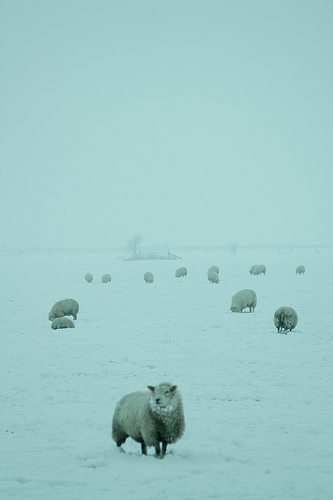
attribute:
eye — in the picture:
[165, 390, 170, 397]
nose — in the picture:
[151, 398, 169, 411]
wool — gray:
[239, 293, 251, 302]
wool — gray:
[284, 308, 297, 314]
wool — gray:
[62, 300, 72, 306]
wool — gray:
[58, 318, 66, 322]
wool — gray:
[210, 270, 214, 276]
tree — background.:
[133, 225, 172, 263]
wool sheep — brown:
[174, 266, 248, 313]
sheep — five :
[273, 306, 296, 336]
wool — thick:
[50, 300, 76, 315]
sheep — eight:
[207, 261, 223, 285]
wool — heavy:
[110, 391, 185, 443]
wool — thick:
[128, 399, 143, 417]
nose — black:
[154, 397, 163, 403]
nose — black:
[152, 395, 162, 405]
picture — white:
[1, 1, 328, 497]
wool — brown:
[64, 302, 74, 309]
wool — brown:
[104, 275, 108, 279]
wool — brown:
[146, 273, 150, 277]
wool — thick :
[117, 402, 153, 427]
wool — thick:
[121, 400, 148, 431]